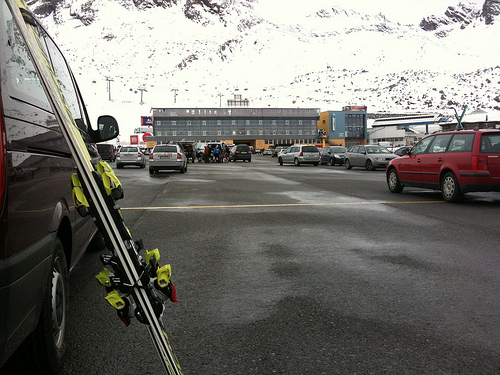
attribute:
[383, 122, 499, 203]
car — red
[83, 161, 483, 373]
pavement — grey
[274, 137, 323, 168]
car — silver